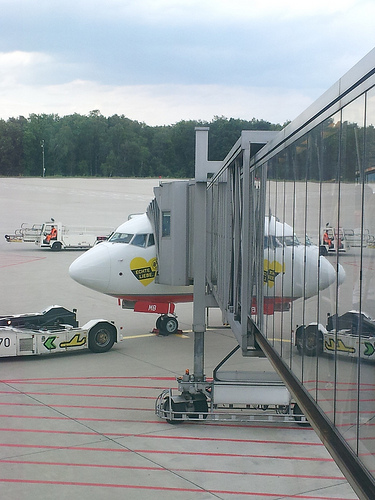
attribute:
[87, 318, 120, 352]
wheel — black, round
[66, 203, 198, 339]
plane — design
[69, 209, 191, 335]
plane — white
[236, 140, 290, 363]
line — red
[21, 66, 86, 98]
clouds — white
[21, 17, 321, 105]
clouds — white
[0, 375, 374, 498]
lines — red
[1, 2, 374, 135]
sky — blue, overcast, cloudy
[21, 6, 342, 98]
clouds — white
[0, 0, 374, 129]
clouds — white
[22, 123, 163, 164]
green trees — many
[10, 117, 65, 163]
trees — green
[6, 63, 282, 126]
clouds — white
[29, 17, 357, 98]
sky — blue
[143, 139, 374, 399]
bridge — loading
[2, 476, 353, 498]
line — red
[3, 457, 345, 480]
line — red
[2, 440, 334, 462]
line — red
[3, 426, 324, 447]
line — red